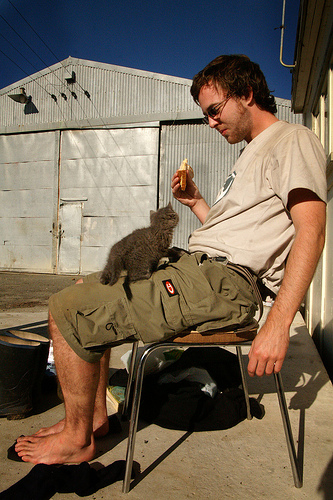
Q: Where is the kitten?
A: Man's lap.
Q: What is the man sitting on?
A: Chair.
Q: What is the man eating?
A: Sandwich.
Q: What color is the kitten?
A: Grey.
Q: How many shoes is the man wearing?
A: None.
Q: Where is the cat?
A: On man's lap.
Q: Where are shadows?
A: On the ground.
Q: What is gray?
A: Cat.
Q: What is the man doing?
A: Eating.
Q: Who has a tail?
A: The cat.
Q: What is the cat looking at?
A: Sandwich.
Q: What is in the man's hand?
A: Sandwich.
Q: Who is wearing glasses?
A: The man.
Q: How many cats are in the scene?
A: One.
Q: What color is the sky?
A: Blue.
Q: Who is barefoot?
A: The man.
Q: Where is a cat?
A: On man's lap.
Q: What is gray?
A: Cat.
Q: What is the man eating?
A: A sandwich.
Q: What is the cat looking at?
A: Man's sandwich.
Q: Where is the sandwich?
A: In man's hand.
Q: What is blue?
A: Sky.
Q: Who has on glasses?
A: The man.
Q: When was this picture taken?
A: Daytime.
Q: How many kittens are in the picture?
A: One.